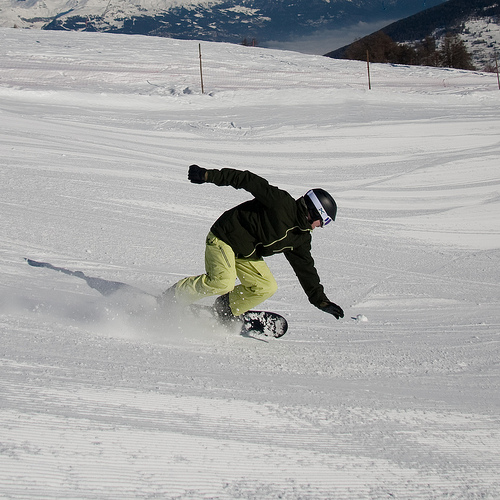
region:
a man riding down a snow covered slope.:
[136, 153, 381, 348]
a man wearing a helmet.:
[290, 182, 352, 229]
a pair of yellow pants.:
[164, 239, 275, 322]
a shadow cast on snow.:
[20, 255, 161, 323]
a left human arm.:
[275, 239, 371, 349]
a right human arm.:
[175, 152, 284, 210]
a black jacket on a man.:
[181, 156, 360, 333]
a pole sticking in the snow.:
[186, 37, 211, 100]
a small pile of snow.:
[351, 308, 377, 330]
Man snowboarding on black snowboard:
[155, 164, 345, 339]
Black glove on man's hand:
[186, 163, 206, 184]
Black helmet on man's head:
[303, 188, 338, 227]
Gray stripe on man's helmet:
[306, 185, 331, 224]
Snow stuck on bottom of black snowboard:
[246, 310, 288, 340]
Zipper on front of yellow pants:
[216, 245, 231, 267]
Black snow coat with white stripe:
[206, 168, 326, 303]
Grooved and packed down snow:
[2, 382, 498, 498]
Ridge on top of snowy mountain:
[2, 70, 499, 106]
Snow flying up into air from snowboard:
[22, 275, 245, 338]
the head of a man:
[302, 153, 360, 244]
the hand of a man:
[167, 131, 249, 205]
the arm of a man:
[171, 153, 359, 217]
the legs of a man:
[150, 193, 328, 331]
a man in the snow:
[141, 81, 442, 351]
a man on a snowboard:
[95, 132, 397, 347]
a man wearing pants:
[150, 208, 291, 353]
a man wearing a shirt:
[174, 146, 396, 254]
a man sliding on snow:
[95, 123, 415, 385]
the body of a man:
[190, 111, 425, 311]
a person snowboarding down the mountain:
[112, 164, 344, 339]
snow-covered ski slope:
[12, 103, 498, 493]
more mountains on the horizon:
[7, 1, 498, 73]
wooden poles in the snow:
[193, 44, 495, 94]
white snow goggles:
[307, 190, 330, 227]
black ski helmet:
[305, 190, 335, 222]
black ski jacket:
[207, 168, 330, 308]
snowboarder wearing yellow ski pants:
[165, 231, 276, 313]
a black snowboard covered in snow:
[127, 294, 287, 340]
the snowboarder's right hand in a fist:
[187, 163, 204, 185]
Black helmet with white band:
[301, 187, 338, 230]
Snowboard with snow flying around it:
[244, 311, 287, 334]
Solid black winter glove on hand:
[186, 162, 207, 184]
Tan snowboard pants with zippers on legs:
[207, 248, 267, 297]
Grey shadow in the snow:
[29, 257, 124, 296]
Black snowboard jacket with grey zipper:
[216, 220, 308, 256]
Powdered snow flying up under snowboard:
[104, 292, 195, 327]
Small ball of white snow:
[351, 312, 371, 325]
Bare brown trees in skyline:
[370, 35, 399, 60]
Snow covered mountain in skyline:
[463, 20, 495, 67]